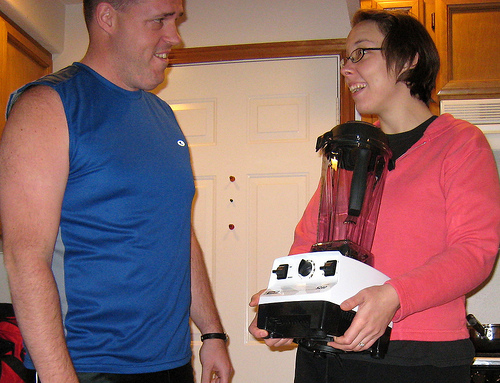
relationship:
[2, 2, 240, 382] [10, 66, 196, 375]
man wearing shirt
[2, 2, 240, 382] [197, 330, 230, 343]
man wearing watch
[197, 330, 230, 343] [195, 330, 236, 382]
watch on left hand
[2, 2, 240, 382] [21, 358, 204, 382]
man wearing pants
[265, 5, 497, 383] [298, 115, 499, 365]
woman wearing sweater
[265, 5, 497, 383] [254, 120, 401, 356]
woman holding blender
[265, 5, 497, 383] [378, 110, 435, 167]
woman wearing shirt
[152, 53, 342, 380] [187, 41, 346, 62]
door has frame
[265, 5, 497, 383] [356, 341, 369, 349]
woman wearing ring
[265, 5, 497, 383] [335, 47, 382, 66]
woman wearing glasses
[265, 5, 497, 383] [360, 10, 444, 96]
woman has hair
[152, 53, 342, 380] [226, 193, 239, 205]
door has peep hole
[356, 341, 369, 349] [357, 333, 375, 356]
ring on finger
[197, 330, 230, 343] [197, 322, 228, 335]
watch on wrist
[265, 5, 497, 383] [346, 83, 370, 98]
woman has open mouth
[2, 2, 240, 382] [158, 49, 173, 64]
man has open mouth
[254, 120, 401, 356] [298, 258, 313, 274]
blender has knob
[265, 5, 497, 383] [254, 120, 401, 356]
woman hold appliance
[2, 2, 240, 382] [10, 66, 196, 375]
man wearing muscle shirt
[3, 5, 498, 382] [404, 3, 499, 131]
people standing in kitchen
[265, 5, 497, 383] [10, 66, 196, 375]
woman wearing shirt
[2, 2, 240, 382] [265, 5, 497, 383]
man staring at woman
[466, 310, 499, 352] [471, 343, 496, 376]
pot on stove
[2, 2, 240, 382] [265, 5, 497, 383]
man standing by woman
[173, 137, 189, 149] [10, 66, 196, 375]
logo on shirt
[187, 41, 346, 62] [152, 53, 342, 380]
trim around door